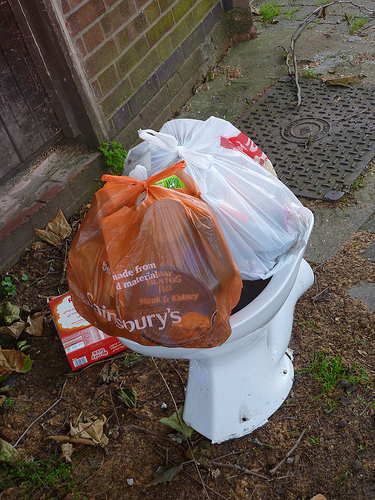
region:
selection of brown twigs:
[238, 432, 314, 474]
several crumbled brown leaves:
[58, 420, 119, 454]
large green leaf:
[154, 412, 194, 438]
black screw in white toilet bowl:
[236, 413, 261, 428]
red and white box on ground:
[36, 297, 115, 366]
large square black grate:
[247, 64, 371, 181]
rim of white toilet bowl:
[231, 299, 301, 319]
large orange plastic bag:
[63, 207, 220, 367]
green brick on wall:
[105, 49, 144, 79]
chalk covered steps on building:
[17, 149, 81, 212]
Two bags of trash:
[86, 123, 285, 334]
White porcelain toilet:
[151, 286, 342, 432]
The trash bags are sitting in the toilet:
[102, 154, 321, 442]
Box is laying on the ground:
[46, 282, 132, 364]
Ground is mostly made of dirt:
[32, 336, 359, 483]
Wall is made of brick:
[1, 102, 162, 224]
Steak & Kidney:
[130, 288, 221, 303]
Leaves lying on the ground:
[2, 282, 106, 464]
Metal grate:
[240, 52, 373, 208]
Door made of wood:
[8, 78, 65, 165]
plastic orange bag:
[56, 153, 264, 361]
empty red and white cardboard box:
[35, 282, 144, 374]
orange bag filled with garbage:
[58, 168, 255, 362]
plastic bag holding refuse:
[54, 154, 263, 362]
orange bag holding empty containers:
[49, 151, 246, 369]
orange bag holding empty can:
[54, 159, 253, 365]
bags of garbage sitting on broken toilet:
[53, 86, 326, 368]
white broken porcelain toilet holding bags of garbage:
[56, 103, 329, 452]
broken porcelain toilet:
[113, 227, 323, 448]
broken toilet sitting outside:
[103, 216, 338, 446]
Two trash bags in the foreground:
[36, 106, 322, 365]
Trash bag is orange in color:
[62, 158, 244, 353]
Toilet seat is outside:
[97, 194, 337, 450]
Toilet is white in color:
[114, 200, 337, 455]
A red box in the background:
[38, 283, 131, 381]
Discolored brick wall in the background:
[61, 0, 249, 132]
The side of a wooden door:
[3, 6, 73, 174]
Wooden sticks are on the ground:
[10, 375, 316, 495]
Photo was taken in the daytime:
[5, 2, 370, 498]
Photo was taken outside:
[7, 7, 374, 498]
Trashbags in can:
[65, 125, 309, 318]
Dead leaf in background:
[39, 210, 70, 246]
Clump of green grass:
[310, 349, 371, 415]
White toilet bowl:
[110, 307, 310, 424]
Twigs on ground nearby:
[179, 453, 295, 486]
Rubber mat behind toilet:
[242, 66, 365, 199]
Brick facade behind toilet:
[60, 6, 220, 90]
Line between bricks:
[95, 20, 108, 40]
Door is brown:
[0, 54, 72, 134]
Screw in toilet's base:
[234, 410, 256, 423]